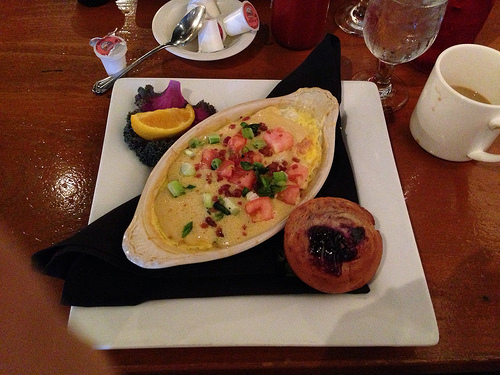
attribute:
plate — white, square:
[70, 76, 439, 345]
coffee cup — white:
[409, 43, 500, 162]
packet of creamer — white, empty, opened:
[88, 29, 127, 76]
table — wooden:
[2, 1, 500, 371]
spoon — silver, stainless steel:
[92, 6, 206, 93]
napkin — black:
[34, 34, 367, 306]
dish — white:
[121, 86, 339, 271]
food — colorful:
[147, 105, 323, 249]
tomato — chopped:
[245, 197, 273, 221]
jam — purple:
[309, 220, 365, 277]